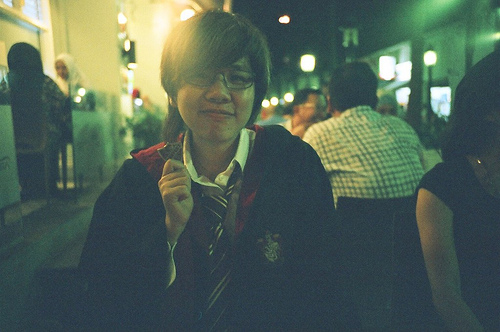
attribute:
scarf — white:
[66, 48, 97, 83]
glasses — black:
[179, 66, 266, 104]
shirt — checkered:
[309, 101, 436, 199]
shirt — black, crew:
[413, 150, 498, 325]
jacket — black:
[78, 124, 333, 328]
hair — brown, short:
[118, 13, 303, 123]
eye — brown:
[215, 73, 255, 93]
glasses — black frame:
[180, 62, 258, 92]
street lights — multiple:
[276, 16, 450, 95]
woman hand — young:
[158, 154, 195, 247]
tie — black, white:
[195, 184, 235, 329]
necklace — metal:
[476, 152, 498, 181]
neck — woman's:
[479, 128, 499, 199]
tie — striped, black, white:
[184, 187, 250, 329]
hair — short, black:
[165, 22, 289, 64]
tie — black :
[201, 165, 241, 330]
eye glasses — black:
[171, 61, 258, 93]